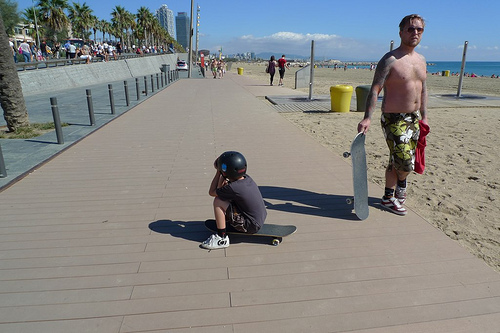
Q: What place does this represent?
A: It represents the beach.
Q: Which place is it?
A: It is a beach.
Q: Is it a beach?
A: Yes, it is a beach.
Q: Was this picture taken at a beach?
A: Yes, it was taken in a beach.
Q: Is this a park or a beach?
A: It is a beach.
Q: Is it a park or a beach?
A: It is a beach.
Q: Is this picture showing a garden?
A: No, the picture is showing a beach.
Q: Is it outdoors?
A: Yes, it is outdoors.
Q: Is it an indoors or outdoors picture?
A: It is outdoors.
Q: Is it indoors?
A: No, it is outdoors.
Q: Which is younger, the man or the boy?
A: The boy is younger than the man.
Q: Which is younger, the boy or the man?
A: The boy is younger than the man.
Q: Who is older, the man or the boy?
A: The man is older than the boy.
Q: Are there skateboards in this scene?
A: Yes, there is a skateboard.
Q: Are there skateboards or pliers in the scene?
A: Yes, there is a skateboard.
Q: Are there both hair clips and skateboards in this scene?
A: No, there is a skateboard but no hair clips.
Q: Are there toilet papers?
A: No, there are no toilet papers.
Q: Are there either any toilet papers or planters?
A: No, there are no toilet papers or planters.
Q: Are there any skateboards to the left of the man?
A: Yes, there is a skateboard to the left of the man.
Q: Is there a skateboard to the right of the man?
A: No, the skateboard is to the left of the man.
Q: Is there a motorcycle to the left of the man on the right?
A: No, there is a skateboard to the left of the man.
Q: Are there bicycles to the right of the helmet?
A: No, there is a skateboard to the right of the helmet.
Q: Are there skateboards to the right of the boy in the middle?
A: Yes, there is a skateboard to the right of the boy.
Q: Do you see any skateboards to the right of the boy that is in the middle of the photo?
A: Yes, there is a skateboard to the right of the boy.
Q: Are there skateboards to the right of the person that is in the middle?
A: Yes, there is a skateboard to the right of the boy.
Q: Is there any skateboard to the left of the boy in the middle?
A: No, the skateboard is to the right of the boy.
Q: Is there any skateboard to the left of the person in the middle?
A: No, the skateboard is to the right of the boy.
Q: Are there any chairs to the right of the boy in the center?
A: No, there is a skateboard to the right of the boy.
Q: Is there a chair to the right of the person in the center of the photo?
A: No, there is a skateboard to the right of the boy.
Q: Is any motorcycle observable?
A: No, there are no motorcycles.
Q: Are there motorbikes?
A: No, there are no motorbikes.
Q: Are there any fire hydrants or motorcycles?
A: No, there are no motorcycles or fire hydrants.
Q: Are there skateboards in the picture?
A: Yes, there is a skateboard.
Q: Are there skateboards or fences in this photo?
A: Yes, there is a skateboard.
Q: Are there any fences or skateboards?
A: Yes, there is a skateboard.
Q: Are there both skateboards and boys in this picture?
A: Yes, there are both a skateboard and a boy.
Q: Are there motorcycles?
A: No, there are no motorcycles.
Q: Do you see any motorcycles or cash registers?
A: No, there are no motorcycles or cash registers.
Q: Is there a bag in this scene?
A: No, there are no bags.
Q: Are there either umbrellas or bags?
A: No, there are no bags or umbrellas.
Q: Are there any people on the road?
A: Yes, there are people on the road.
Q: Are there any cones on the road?
A: No, there are people on the road.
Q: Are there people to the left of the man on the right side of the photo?
A: Yes, there is a person to the left of the man.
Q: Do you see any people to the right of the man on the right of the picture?
A: No, the person is to the left of the man.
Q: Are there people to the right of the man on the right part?
A: No, the person is to the left of the man.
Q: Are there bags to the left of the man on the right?
A: No, there is a person to the left of the man.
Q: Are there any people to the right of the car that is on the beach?
A: Yes, there is a person to the right of the car.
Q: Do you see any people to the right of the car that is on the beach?
A: Yes, there is a person to the right of the car.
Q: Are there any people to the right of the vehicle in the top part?
A: Yes, there is a person to the right of the car.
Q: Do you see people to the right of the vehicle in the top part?
A: Yes, there is a person to the right of the car.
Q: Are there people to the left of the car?
A: No, the person is to the right of the car.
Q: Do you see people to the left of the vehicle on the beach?
A: No, the person is to the right of the car.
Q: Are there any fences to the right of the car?
A: No, there is a person to the right of the car.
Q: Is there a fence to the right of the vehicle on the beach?
A: No, there is a person to the right of the car.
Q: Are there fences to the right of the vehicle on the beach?
A: No, there is a person to the right of the car.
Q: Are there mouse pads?
A: No, there are no mouse pads.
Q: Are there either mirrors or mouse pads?
A: No, there are no mouse pads or mirrors.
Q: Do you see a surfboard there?
A: No, there are no surfboards.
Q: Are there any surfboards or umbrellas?
A: No, there are no surfboards or umbrellas.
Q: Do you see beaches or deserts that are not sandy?
A: No, there is a beach but it is sandy.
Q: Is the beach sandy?
A: Yes, the beach is sandy.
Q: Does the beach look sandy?
A: Yes, the beach is sandy.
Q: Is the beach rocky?
A: No, the beach is sandy.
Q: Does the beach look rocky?
A: No, the beach is sandy.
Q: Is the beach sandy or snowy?
A: The beach is sandy.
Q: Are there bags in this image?
A: No, there are no bags.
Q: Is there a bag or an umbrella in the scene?
A: No, there are no bags or umbrellas.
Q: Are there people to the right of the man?
A: Yes, there are people to the right of the man.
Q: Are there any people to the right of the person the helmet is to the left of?
A: Yes, there are people to the right of the man.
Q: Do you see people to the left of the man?
A: No, the people are to the right of the man.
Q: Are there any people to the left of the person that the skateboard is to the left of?
A: No, the people are to the right of the man.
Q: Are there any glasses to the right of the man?
A: No, there are people to the right of the man.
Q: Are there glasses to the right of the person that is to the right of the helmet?
A: No, there are people to the right of the man.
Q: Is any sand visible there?
A: Yes, there is sand.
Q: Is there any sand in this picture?
A: Yes, there is sand.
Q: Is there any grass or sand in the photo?
A: Yes, there is sand.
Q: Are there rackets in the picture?
A: No, there are no rackets.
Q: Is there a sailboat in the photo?
A: No, there are no sailboats.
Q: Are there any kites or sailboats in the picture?
A: No, there are no sailboats or kites.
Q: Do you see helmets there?
A: Yes, there is a helmet.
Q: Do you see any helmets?
A: Yes, there is a helmet.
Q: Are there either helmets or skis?
A: Yes, there is a helmet.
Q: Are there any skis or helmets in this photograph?
A: Yes, there is a helmet.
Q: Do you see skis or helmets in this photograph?
A: Yes, there is a helmet.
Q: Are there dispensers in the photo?
A: No, there are no dispensers.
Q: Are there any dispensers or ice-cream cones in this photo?
A: No, there are no dispensers or ice-cream cones.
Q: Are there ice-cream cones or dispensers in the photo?
A: No, there are no dispensers or ice-cream cones.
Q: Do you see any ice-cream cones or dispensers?
A: No, there are no dispensers or ice-cream cones.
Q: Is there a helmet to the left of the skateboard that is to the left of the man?
A: Yes, there is a helmet to the left of the skateboard.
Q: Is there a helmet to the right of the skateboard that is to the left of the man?
A: No, the helmet is to the left of the skateboard.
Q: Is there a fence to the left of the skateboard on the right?
A: No, there is a helmet to the left of the skateboard.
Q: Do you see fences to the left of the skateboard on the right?
A: No, there is a helmet to the left of the skateboard.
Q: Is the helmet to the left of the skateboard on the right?
A: Yes, the helmet is to the left of the skateboard.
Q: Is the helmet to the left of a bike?
A: No, the helmet is to the left of the skateboard.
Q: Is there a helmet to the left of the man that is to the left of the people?
A: Yes, there is a helmet to the left of the man.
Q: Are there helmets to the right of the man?
A: No, the helmet is to the left of the man.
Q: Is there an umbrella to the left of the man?
A: No, there is a helmet to the left of the man.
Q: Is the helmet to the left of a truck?
A: No, the helmet is to the left of a man.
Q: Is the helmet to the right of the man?
A: No, the helmet is to the left of the man.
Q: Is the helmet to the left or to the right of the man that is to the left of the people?
A: The helmet is to the left of the man.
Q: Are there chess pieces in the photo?
A: No, there are no chess pieces.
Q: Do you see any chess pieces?
A: No, there are no chess pieces.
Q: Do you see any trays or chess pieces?
A: No, there are no chess pieces or trays.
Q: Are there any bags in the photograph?
A: No, there are no bags.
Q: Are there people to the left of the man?
A: Yes, there is a person to the left of the man.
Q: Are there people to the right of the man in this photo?
A: No, the person is to the left of the man.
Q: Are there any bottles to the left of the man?
A: No, there is a person to the left of the man.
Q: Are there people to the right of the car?
A: Yes, there is a person to the right of the car.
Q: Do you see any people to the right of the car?
A: Yes, there is a person to the right of the car.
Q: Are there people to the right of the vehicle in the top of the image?
A: Yes, there is a person to the right of the car.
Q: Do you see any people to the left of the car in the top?
A: No, the person is to the right of the car.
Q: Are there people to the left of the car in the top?
A: No, the person is to the right of the car.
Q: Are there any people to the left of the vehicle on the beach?
A: No, the person is to the right of the car.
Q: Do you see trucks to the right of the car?
A: No, there is a person to the right of the car.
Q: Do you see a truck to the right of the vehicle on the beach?
A: No, there is a person to the right of the car.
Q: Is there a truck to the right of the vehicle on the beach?
A: No, there is a person to the right of the car.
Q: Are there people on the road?
A: Yes, there are people on the road.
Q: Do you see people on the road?
A: Yes, there are people on the road.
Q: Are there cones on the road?
A: No, there are people on the road.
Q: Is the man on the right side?
A: Yes, the man is on the right of the image.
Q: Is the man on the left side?
A: No, the man is on the right of the image.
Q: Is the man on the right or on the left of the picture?
A: The man is on the right of the image.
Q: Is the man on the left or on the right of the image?
A: The man is on the right of the image.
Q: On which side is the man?
A: The man is on the right of the image.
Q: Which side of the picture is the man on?
A: The man is on the right of the image.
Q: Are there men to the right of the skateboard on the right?
A: Yes, there is a man to the right of the skateboard.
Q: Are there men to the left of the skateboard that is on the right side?
A: No, the man is to the right of the skateboard.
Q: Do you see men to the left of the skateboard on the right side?
A: No, the man is to the right of the skateboard.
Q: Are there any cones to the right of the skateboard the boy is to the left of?
A: No, there is a man to the right of the skateboard.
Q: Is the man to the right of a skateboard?
A: Yes, the man is to the right of a skateboard.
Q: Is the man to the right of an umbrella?
A: No, the man is to the right of a skateboard.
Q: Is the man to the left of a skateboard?
A: No, the man is to the right of a skateboard.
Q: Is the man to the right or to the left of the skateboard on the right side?
A: The man is to the right of the skateboard.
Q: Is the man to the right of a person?
A: Yes, the man is to the right of a person.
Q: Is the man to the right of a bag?
A: No, the man is to the right of a person.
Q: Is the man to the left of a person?
A: No, the man is to the right of a person.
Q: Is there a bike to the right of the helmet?
A: No, there is a man to the right of the helmet.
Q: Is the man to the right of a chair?
A: No, the man is to the right of the helmet.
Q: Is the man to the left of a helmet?
A: No, the man is to the right of a helmet.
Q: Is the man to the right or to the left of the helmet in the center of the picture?
A: The man is to the right of the helmet.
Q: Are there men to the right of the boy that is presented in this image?
A: Yes, there is a man to the right of the boy.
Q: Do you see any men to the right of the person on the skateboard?
A: Yes, there is a man to the right of the boy.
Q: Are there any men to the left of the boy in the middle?
A: No, the man is to the right of the boy.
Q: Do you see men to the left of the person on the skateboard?
A: No, the man is to the right of the boy.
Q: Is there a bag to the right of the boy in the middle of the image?
A: No, there is a man to the right of the boy.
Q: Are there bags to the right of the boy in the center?
A: No, there is a man to the right of the boy.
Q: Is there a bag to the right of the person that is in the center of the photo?
A: No, there is a man to the right of the boy.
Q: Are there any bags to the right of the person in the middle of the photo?
A: No, there is a man to the right of the boy.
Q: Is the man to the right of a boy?
A: Yes, the man is to the right of a boy.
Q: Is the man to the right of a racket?
A: No, the man is to the right of a boy.